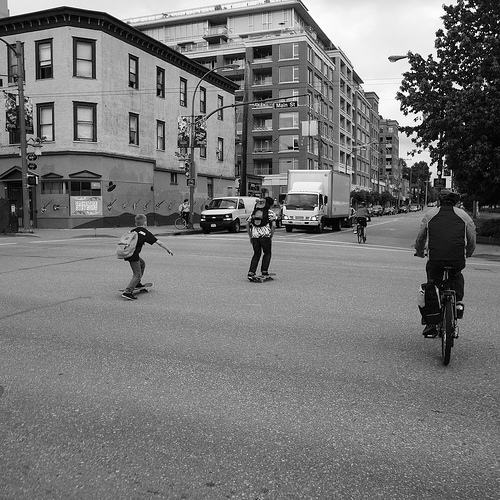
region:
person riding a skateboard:
[99, 210, 173, 317]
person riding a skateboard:
[246, 203, 281, 297]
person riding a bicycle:
[398, 185, 478, 366]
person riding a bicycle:
[356, 205, 376, 252]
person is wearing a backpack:
[254, 204, 283, 240]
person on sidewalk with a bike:
[170, 195, 197, 230]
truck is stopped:
[284, 166, 338, 236]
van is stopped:
[200, 198, 246, 229]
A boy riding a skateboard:
[117, 212, 175, 302]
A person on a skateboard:
[247, 193, 279, 285]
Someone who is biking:
[414, 188, 477, 365]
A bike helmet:
[434, 188, 460, 204]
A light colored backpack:
[117, 231, 139, 258]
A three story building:
[0, 4, 240, 234]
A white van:
[202, 194, 263, 231]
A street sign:
[274, 101, 299, 108]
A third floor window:
[72, 35, 98, 79]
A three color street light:
[436, 158, 444, 178]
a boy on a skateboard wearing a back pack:
[111, 204, 179, 301]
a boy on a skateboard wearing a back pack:
[242, 191, 287, 282]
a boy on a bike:
[409, 184, 482, 369]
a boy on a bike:
[346, 197, 378, 248]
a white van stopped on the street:
[196, 192, 266, 234]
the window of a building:
[124, 107, 144, 148]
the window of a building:
[68, 97, 100, 146]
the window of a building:
[68, 33, 100, 82]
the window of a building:
[31, 98, 61, 146]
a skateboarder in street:
[118, 211, 174, 301]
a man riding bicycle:
[414, 190, 479, 365]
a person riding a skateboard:
[244, 190, 279, 284]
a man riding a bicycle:
[353, 198, 371, 244]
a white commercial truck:
[281, 166, 351, 234]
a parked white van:
[200, 195, 257, 230]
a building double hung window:
[73, 101, 94, 141]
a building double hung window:
[72, 35, 92, 76]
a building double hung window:
[129, 55, 138, 87]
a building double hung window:
[129, 112, 139, 144]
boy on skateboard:
[111, 210, 178, 303]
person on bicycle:
[412, 182, 481, 372]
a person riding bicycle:
[346, 194, 378, 247]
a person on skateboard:
[243, 193, 280, 284]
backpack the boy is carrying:
[113, 229, 138, 261]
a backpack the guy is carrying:
[249, 195, 271, 227]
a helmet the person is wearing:
[434, 185, 463, 203]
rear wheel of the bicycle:
[437, 298, 460, 369]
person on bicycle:
[172, 195, 194, 230]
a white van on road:
[196, 193, 262, 233]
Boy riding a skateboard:
[106, 204, 185, 307]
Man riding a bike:
[401, 177, 483, 367]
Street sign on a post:
[268, 94, 304, 117]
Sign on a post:
[173, 111, 210, 153]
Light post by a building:
[174, 57, 248, 237]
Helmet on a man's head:
[437, 185, 465, 206]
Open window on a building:
[32, 40, 57, 84]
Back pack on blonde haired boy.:
[118, 228, 138, 260]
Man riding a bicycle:
[424, 187, 471, 357]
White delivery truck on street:
[281, 173, 354, 228]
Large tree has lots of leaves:
[388, 4, 498, 203]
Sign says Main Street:
[266, 100, 304, 110]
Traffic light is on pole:
[180, 157, 195, 182]